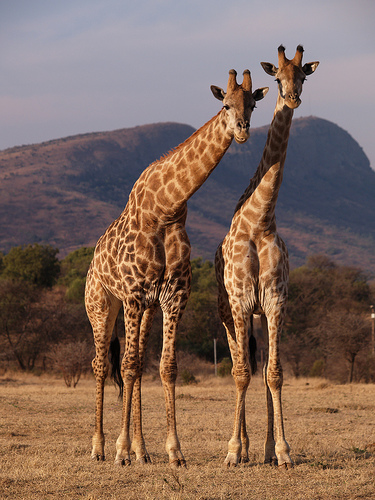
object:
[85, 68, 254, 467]
giraffe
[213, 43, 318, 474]
giraffe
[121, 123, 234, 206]
neck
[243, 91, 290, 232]
neck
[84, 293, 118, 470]
legs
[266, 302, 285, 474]
legs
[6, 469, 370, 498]
grass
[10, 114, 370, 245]
hill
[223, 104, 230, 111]
eye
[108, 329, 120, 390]
tail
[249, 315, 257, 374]
tail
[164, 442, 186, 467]
hooves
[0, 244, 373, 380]
trees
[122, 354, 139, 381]
joint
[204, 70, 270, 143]
head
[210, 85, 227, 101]
ear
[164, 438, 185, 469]
hoof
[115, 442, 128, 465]
hoof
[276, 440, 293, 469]
hoof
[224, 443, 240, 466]
hoof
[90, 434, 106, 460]
hoof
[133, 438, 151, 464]
hoof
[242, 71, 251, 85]
horns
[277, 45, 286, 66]
horns